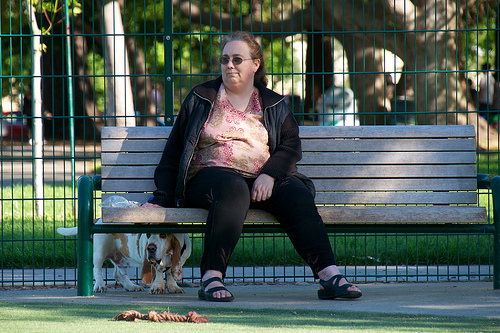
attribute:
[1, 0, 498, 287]
fence — metal, green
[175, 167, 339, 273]
pants — black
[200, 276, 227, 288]
black strap — thick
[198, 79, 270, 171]
shirt — yellow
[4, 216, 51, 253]
grass — green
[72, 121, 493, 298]
bench — wooden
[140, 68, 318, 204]
jacket — open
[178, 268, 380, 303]
sandals — black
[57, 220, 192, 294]
dog — brown and white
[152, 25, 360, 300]
woman — pink, flowery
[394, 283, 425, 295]
surface — concrete, grey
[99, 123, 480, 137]
slats — tan, wooden